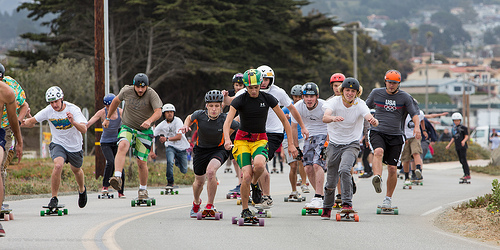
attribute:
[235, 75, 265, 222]
boy — skateboarding, determined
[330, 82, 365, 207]
man — young, shirtless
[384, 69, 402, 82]
helmet — orange, green, black, yellow, red, gray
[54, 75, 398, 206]
people — skateboarding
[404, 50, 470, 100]
houses — background, tan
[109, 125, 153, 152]
shorts — red, green, multi colored, multicolored, colored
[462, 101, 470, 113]
telephone — brown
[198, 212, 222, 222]
wheels — green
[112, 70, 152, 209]
person — skateboarding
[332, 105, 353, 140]
shirt — black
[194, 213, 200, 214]
shoe strings — red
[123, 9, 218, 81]
trees — brown, fir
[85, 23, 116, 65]
pole — wooden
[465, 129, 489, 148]
truck — white